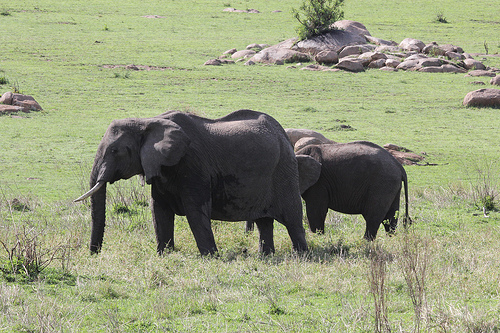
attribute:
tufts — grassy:
[1, 200, 86, 285]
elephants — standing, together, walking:
[76, 103, 425, 267]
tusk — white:
[71, 182, 105, 204]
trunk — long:
[89, 145, 109, 260]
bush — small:
[0, 214, 71, 286]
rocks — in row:
[201, 17, 499, 112]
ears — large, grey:
[138, 112, 190, 184]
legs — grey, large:
[142, 192, 226, 258]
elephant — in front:
[70, 107, 310, 263]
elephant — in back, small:
[283, 124, 415, 245]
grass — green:
[3, 194, 499, 302]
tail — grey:
[399, 167, 414, 229]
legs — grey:
[255, 141, 310, 263]